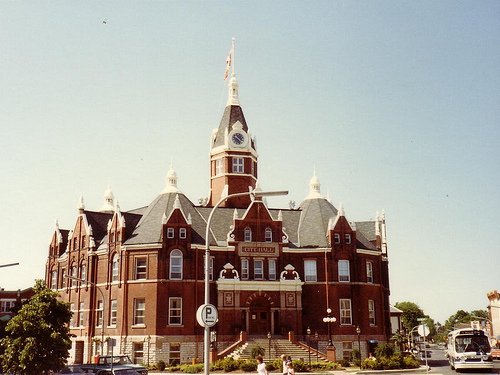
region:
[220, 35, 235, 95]
THIS IS A FLAG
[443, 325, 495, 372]
THIS IS A BUS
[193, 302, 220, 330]
THIS A PARKING SIGN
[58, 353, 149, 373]
THIS IS A BLUE TRUCK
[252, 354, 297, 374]
WHERE ARE THESE PEOPLE GOING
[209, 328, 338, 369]
THESE ARE BRICK STEPS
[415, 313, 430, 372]
THIS IS A STREET SIGN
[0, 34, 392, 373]
THIS IS A BIG CHURCH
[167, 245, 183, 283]
THIS IS A BIG WINDOW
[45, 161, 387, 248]
THIS IS THE ROOF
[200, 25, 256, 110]
white steeple of building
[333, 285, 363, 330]
window on red building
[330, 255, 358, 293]
window on red building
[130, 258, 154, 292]
window on red building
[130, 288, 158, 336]
window on red building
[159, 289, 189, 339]
window on red building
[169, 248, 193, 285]
window on red building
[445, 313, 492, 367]
bus on the road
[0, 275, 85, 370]
tall green leafy tree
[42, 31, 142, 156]
clear cloudless blue sky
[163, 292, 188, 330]
a window in a building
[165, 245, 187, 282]
a window in a building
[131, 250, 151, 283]
a window in a building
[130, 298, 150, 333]
a window in a building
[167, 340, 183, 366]
a window in a building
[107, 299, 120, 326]
a window in a building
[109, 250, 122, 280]
a window in a building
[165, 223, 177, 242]
a window in a building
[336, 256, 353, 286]
a window in a building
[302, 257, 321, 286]
a window in a building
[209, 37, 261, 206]
a clock tower on the building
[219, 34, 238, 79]
a flag on the top of the clock tower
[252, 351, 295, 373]
a group of people walking down the street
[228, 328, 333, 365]
stairs leading up to the building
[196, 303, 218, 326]
a parking sign on a light pole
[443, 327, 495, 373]
a bus traveling down the street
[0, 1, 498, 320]
a clear blue sky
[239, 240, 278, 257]
a sign on the front of the building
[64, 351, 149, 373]
a blue pickup truck on the street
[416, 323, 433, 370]
a stop sign on the corner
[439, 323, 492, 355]
a bus on the road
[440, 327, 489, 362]
a bus on teh street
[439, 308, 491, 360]
a white bus on the road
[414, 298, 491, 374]
a white bus on the street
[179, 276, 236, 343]
a sign on the pole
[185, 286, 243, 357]
a sign on a metal pole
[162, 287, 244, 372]
a pole with a sign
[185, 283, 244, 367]
a metal pole with sign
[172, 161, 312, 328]
a street light on a pole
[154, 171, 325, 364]
a street light on a metal pole